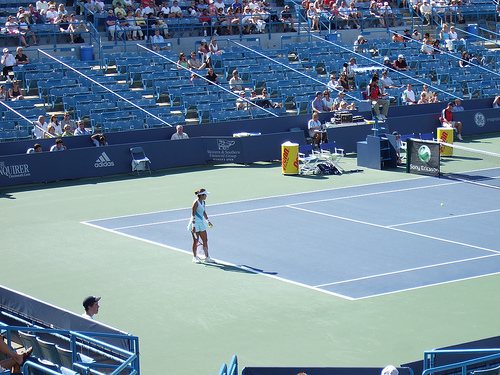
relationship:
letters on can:
[281, 145, 291, 172] [280, 142, 300, 177]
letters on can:
[292, 153, 299, 170] [280, 142, 300, 177]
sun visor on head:
[198, 189, 210, 196] [193, 187, 209, 202]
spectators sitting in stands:
[399, 18, 465, 52] [6, 2, 496, 145]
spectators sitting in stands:
[26, 116, 103, 138] [6, 2, 496, 145]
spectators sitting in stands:
[173, 41, 220, 69] [6, 2, 496, 145]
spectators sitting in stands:
[4, 2, 88, 37] [6, 2, 496, 145]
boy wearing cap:
[77, 294, 102, 324] [197, 188, 218, 196]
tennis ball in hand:
[207, 222, 213, 227] [208, 220, 213, 228]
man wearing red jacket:
[368, 73, 388, 107] [363, 81, 386, 98]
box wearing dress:
[187, 189, 214, 263] [188, 197, 210, 234]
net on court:
[404, 137, 499, 189] [59, 143, 498, 308]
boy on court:
[82, 296, 102, 319] [0, 134, 497, 373]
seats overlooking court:
[58, 55, 231, 117] [0, 134, 497, 373]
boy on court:
[82, 296, 102, 319] [9, 24, 475, 374]